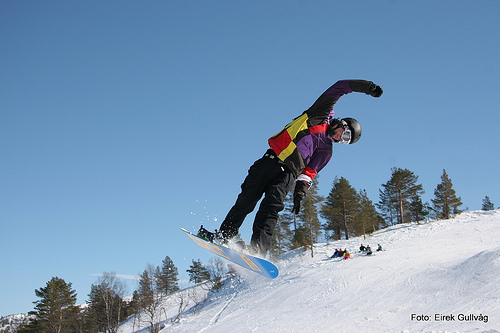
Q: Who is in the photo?
A: A man.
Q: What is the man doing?
A: Snowboarding.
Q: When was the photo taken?
A: During the day.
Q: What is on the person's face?
A: Glasses.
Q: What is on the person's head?
A: A helmet.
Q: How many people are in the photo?
A: One.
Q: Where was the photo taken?
A: Outdoors in the snow.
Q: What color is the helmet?
A: Black.